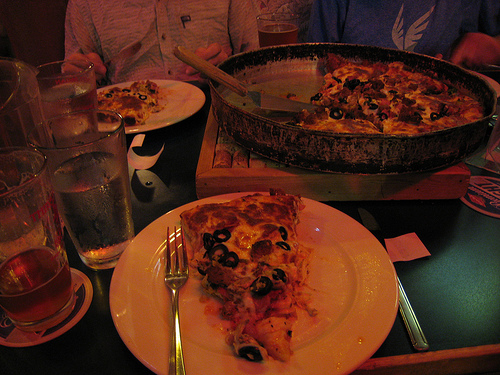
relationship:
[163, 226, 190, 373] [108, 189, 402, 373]
fork on plate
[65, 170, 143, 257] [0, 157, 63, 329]
liquid in glass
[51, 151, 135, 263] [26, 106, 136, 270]
liquid in glass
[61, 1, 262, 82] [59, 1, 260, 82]
man of man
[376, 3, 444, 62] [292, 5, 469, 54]
symbol on shirt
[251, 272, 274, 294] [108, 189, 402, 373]
olive on plate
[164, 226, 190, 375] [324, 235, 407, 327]
fork on plate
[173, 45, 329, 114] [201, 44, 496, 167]
handle in pizza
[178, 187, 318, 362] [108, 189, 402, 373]
cheese on plate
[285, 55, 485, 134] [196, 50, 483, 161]
pizza in pan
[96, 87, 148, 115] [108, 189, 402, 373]
pizza in plate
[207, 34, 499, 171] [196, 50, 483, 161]
pizza in pan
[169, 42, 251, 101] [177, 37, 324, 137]
handle on spatula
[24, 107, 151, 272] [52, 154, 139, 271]
glass with water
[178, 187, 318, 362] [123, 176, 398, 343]
cheese on plate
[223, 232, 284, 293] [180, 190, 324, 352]
toppings on pizza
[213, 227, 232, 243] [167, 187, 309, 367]
olive on pizza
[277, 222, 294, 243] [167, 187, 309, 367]
olives on pizza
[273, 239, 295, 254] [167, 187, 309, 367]
olives on pizza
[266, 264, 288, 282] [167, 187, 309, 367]
olives on pizza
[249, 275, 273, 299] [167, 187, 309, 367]
olive on pizza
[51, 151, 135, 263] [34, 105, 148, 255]
liquid in glass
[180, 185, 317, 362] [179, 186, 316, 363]
cheese on pizza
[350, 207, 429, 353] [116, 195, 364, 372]
knife by plate